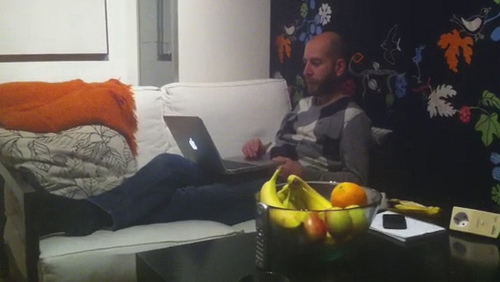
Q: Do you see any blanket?
A: Yes, there is a blanket.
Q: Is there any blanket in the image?
A: Yes, there is a blanket.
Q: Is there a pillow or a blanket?
A: Yes, there is a blanket.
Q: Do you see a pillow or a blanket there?
A: Yes, there is a blanket.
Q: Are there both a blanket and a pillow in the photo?
A: Yes, there are both a blanket and a pillow.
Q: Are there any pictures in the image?
A: No, there are no pictures.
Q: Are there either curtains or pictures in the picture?
A: No, there are no pictures or curtains.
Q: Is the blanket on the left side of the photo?
A: Yes, the blanket is on the left of the image.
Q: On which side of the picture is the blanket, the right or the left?
A: The blanket is on the left of the image.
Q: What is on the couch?
A: The blanket is on the couch.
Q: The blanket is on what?
A: The blanket is on the couch.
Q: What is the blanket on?
A: The blanket is on the couch.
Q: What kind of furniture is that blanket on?
A: The blanket is on the couch.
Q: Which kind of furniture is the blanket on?
A: The blanket is on the couch.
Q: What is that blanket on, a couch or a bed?
A: The blanket is on a couch.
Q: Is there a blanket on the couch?
A: Yes, there is a blanket on the couch.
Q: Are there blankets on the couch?
A: Yes, there is a blanket on the couch.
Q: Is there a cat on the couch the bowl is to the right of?
A: No, there is a blanket on the couch.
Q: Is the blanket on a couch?
A: Yes, the blanket is on a couch.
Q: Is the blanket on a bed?
A: No, the blanket is on a couch.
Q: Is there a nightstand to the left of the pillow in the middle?
A: No, there is a blanket to the left of the pillow.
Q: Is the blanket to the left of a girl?
A: No, the blanket is to the left of the pillow.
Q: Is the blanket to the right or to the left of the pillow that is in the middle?
A: The blanket is to the left of the pillow.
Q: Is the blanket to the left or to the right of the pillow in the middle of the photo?
A: The blanket is to the left of the pillow.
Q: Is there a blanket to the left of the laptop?
A: Yes, there is a blanket to the left of the laptop.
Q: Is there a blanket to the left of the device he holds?
A: Yes, there is a blanket to the left of the laptop.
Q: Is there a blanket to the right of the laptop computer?
A: No, the blanket is to the left of the laptop computer.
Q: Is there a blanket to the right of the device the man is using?
A: No, the blanket is to the left of the laptop computer.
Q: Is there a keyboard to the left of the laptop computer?
A: No, there is a blanket to the left of the laptop computer.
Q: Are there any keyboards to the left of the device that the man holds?
A: No, there is a blanket to the left of the laptop computer.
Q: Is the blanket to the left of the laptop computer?
A: Yes, the blanket is to the left of the laptop computer.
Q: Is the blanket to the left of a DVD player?
A: No, the blanket is to the left of the laptop computer.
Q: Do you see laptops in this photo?
A: Yes, there is a laptop.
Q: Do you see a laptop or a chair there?
A: Yes, there is a laptop.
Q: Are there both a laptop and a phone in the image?
A: Yes, there are both a laptop and a phone.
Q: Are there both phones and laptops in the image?
A: Yes, there are both a laptop and a phone.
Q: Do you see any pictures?
A: No, there are no pictures.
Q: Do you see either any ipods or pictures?
A: No, there are no pictures or ipods.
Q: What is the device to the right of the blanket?
A: The device is a laptop.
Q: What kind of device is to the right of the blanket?
A: The device is a laptop.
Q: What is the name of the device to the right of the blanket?
A: The device is a laptop.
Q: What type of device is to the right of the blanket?
A: The device is a laptop.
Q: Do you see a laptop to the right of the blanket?
A: Yes, there is a laptop to the right of the blanket.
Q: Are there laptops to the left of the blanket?
A: No, the laptop is to the right of the blanket.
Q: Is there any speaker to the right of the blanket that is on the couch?
A: No, there is a laptop to the right of the blanket.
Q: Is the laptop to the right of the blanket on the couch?
A: Yes, the laptop is to the right of the blanket.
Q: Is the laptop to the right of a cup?
A: No, the laptop is to the right of the blanket.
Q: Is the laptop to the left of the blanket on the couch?
A: No, the laptop is to the right of the blanket.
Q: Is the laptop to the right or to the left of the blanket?
A: The laptop is to the right of the blanket.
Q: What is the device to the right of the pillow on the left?
A: The device is a laptop.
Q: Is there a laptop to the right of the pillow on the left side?
A: Yes, there is a laptop to the right of the pillow.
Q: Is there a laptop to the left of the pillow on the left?
A: No, the laptop is to the right of the pillow.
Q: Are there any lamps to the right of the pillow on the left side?
A: No, there is a laptop to the right of the pillow.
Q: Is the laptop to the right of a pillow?
A: Yes, the laptop is to the right of a pillow.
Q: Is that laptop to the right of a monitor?
A: No, the laptop is to the right of a pillow.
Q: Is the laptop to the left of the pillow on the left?
A: No, the laptop is to the right of the pillow.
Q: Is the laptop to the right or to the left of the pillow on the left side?
A: The laptop is to the right of the pillow.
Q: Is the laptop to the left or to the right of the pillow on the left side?
A: The laptop is to the right of the pillow.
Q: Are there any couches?
A: Yes, there is a couch.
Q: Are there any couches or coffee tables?
A: Yes, there is a couch.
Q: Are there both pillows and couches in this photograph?
A: Yes, there are both a couch and pillows.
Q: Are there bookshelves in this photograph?
A: No, there are no bookshelves.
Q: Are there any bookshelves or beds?
A: No, there are no bookshelves or beds.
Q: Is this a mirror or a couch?
A: This is a couch.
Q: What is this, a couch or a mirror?
A: This is a couch.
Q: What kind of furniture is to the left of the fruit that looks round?
A: The piece of furniture is a couch.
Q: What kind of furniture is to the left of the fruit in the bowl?
A: The piece of furniture is a couch.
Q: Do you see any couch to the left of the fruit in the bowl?
A: Yes, there is a couch to the left of the fruit.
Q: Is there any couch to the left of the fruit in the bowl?
A: Yes, there is a couch to the left of the fruit.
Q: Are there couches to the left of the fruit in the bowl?
A: Yes, there is a couch to the left of the fruit.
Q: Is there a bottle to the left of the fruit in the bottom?
A: No, there is a couch to the left of the fruit.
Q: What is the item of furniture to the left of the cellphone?
A: The piece of furniture is a couch.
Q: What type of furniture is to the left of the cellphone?
A: The piece of furniture is a couch.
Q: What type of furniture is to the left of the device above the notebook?
A: The piece of furniture is a couch.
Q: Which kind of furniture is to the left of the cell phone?
A: The piece of furniture is a couch.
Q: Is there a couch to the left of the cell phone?
A: Yes, there is a couch to the left of the cell phone.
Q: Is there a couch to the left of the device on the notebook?
A: Yes, there is a couch to the left of the cell phone.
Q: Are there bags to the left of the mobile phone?
A: No, there is a couch to the left of the mobile phone.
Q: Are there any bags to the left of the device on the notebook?
A: No, there is a couch to the left of the mobile phone.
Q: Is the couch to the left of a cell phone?
A: Yes, the couch is to the left of a cell phone.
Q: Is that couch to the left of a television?
A: No, the couch is to the left of a cell phone.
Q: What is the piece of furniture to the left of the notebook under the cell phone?
A: The piece of furniture is a couch.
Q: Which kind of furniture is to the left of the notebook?
A: The piece of furniture is a couch.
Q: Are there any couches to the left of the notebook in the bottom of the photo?
A: Yes, there is a couch to the left of the notebook.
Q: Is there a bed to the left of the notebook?
A: No, there is a couch to the left of the notebook.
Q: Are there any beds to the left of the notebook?
A: No, there is a couch to the left of the notebook.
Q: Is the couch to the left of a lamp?
A: No, the couch is to the left of the notebook.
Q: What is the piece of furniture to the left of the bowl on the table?
A: The piece of furniture is a couch.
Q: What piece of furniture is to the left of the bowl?
A: The piece of furniture is a couch.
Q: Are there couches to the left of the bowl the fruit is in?
A: Yes, there is a couch to the left of the bowl.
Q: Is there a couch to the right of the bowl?
A: No, the couch is to the left of the bowl.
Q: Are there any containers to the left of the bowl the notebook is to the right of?
A: No, there is a couch to the left of the bowl.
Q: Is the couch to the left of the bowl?
A: Yes, the couch is to the left of the bowl.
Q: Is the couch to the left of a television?
A: No, the couch is to the left of the bowl.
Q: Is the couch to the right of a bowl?
A: No, the couch is to the left of a bowl.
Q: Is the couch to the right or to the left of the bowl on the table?
A: The couch is to the left of the bowl.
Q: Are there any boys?
A: No, there are no boys.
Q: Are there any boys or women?
A: No, there are no boys or women.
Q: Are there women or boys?
A: No, there are no boys or women.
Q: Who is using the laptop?
A: The man is using the laptop.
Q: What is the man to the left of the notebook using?
A: The man is using a laptop.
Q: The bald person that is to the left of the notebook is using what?
A: The man is using a laptop.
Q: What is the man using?
A: The man is using a laptop.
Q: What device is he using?
A: The man is using a laptop computer.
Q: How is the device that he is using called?
A: The device is a laptop.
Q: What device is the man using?
A: The man is using a laptop computer.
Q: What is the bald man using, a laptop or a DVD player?
A: The man is using a laptop.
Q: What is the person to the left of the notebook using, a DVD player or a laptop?
A: The man is using a laptop.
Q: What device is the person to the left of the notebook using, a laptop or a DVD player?
A: The man is using a laptop.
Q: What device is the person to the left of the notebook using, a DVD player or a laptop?
A: The man is using a laptop.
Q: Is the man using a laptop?
A: Yes, the man is using a laptop.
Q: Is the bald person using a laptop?
A: Yes, the man is using a laptop.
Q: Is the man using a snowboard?
A: No, the man is using a laptop.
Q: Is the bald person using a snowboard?
A: No, the man is using a laptop.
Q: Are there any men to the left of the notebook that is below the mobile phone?
A: Yes, there is a man to the left of the notebook.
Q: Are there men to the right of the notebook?
A: No, the man is to the left of the notebook.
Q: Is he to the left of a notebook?
A: Yes, the man is to the left of a notebook.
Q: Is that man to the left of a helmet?
A: No, the man is to the left of a notebook.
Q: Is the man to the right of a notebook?
A: No, the man is to the left of a notebook.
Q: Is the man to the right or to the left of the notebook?
A: The man is to the left of the notebook.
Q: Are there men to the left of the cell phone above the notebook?
A: Yes, there is a man to the left of the cellphone.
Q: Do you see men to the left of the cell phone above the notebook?
A: Yes, there is a man to the left of the cellphone.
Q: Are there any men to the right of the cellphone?
A: No, the man is to the left of the cellphone.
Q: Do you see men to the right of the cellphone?
A: No, the man is to the left of the cellphone.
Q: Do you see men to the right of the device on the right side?
A: No, the man is to the left of the cellphone.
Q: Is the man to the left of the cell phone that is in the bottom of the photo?
A: Yes, the man is to the left of the mobile phone.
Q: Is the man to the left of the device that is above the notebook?
A: Yes, the man is to the left of the mobile phone.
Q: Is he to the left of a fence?
A: No, the man is to the left of the mobile phone.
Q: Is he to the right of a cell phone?
A: No, the man is to the left of a cell phone.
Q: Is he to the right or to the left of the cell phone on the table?
A: The man is to the left of the mobile phone.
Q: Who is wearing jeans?
A: The man is wearing jeans.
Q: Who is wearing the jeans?
A: The man is wearing jeans.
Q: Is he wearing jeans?
A: Yes, the man is wearing jeans.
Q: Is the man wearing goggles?
A: No, the man is wearing jeans.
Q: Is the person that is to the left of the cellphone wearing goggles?
A: No, the man is wearing jeans.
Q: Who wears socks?
A: The man wears socks.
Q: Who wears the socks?
A: The man wears socks.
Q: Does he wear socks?
A: Yes, the man wears socks.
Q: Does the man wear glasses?
A: No, the man wears socks.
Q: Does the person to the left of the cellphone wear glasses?
A: No, the man wears socks.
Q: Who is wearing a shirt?
A: The man is wearing a shirt.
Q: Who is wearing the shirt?
A: The man is wearing a shirt.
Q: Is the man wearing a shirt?
A: Yes, the man is wearing a shirt.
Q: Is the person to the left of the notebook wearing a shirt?
A: Yes, the man is wearing a shirt.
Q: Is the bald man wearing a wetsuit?
A: No, the man is wearing a shirt.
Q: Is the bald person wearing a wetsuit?
A: No, the man is wearing a shirt.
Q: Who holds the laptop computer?
A: The man holds the laptop computer.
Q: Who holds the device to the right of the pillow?
A: The man holds the laptop computer.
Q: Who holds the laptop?
A: The man holds the laptop computer.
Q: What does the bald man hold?
A: The man holds the laptop.